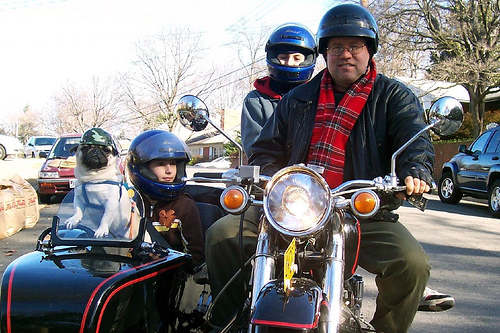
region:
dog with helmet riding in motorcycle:
[63, 123, 200, 273]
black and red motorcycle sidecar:
[6, 195, 204, 332]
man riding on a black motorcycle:
[311, 6, 443, 314]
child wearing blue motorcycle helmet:
[128, 122, 204, 206]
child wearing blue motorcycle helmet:
[258, 21, 324, 115]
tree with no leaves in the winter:
[105, 41, 218, 108]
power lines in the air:
[100, 27, 297, 104]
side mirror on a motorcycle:
[173, 88, 287, 208]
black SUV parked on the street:
[431, 116, 498, 221]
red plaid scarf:
[299, 65, 368, 184]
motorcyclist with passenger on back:
[209, 8, 455, 329]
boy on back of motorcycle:
[241, 25, 316, 155]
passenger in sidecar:
[117, 122, 208, 307]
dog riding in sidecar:
[63, 122, 154, 249]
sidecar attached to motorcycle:
[6, 182, 210, 332]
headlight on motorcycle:
[261, 162, 336, 239]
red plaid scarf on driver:
[309, 57, 380, 197]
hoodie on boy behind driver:
[238, 77, 285, 157]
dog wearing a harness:
[63, 126, 153, 244]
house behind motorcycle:
[191, 127, 243, 166]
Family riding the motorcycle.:
[61, 22, 495, 208]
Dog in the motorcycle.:
[73, 112, 180, 287]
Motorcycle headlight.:
[242, 152, 392, 268]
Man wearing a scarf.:
[286, 10, 442, 268]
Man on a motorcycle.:
[268, 15, 461, 152]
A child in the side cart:
[121, 106, 219, 223]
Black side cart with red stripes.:
[23, 212, 131, 317]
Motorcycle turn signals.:
[209, 182, 249, 214]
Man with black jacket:
[263, 72, 498, 219]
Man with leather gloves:
[403, 163, 478, 224]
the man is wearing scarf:
[295, 15, 352, 160]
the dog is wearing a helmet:
[62, 125, 135, 267]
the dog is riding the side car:
[60, 139, 200, 278]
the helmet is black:
[317, 8, 396, 60]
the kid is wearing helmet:
[116, 121, 190, 231]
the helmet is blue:
[241, 5, 309, 93]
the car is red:
[33, 124, 105, 195]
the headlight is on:
[258, 157, 344, 251]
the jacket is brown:
[132, 187, 222, 268]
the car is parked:
[44, 128, 129, 212]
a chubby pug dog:
[47, 120, 153, 249]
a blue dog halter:
[64, 174, 136, 217]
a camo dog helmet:
[65, 123, 123, 160]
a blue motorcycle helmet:
[119, 116, 209, 205]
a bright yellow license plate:
[273, 218, 321, 298]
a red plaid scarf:
[296, 56, 420, 203]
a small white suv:
[15, 121, 82, 166]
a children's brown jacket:
[123, 192, 213, 281]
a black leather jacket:
[241, 66, 463, 202]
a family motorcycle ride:
[46, 5, 488, 322]